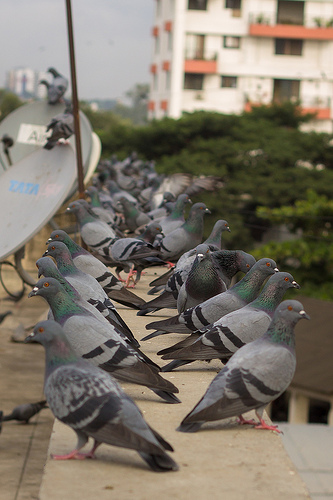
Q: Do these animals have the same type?
A: No, there are both pigeons and birds.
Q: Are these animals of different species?
A: Yes, they are pigeons and birds.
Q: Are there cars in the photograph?
A: No, there are no cars.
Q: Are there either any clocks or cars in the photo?
A: No, there are no cars or clocks.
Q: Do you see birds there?
A: Yes, there is a bird.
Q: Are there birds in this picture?
A: Yes, there is a bird.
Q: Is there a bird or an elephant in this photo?
A: Yes, there is a bird.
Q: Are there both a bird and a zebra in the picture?
A: No, there is a bird but no zebras.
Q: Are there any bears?
A: No, there are no bears.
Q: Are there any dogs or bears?
A: No, there are no bears or dogs.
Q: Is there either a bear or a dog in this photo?
A: No, there are no bears or dogs.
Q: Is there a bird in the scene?
A: Yes, there is a bird.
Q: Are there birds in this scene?
A: Yes, there is a bird.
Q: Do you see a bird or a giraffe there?
A: Yes, there is a bird.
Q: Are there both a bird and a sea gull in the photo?
A: No, there is a bird but no seagulls.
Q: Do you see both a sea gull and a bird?
A: No, there is a bird but no seagulls.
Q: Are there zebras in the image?
A: No, there are no zebras.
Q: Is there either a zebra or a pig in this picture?
A: No, there are no zebras or pigs.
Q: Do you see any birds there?
A: Yes, there is a bird.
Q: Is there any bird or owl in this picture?
A: Yes, there is a bird.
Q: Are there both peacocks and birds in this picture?
A: No, there is a bird but no peacocks.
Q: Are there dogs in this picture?
A: No, there are no dogs.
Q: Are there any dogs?
A: No, there are no dogs.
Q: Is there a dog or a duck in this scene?
A: No, there are no dogs or ducks.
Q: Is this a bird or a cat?
A: This is a bird.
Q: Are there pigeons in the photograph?
A: Yes, there is a pigeon.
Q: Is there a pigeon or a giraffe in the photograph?
A: Yes, there is a pigeon.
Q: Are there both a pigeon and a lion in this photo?
A: No, there is a pigeon but no lions.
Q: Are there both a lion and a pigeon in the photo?
A: No, there is a pigeon but no lions.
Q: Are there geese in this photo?
A: No, there are no geese.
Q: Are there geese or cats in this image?
A: No, there are no geese or cats.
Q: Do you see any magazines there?
A: No, there are no magazines.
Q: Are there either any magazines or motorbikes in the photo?
A: No, there are no magazines or motorbikes.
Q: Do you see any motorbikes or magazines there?
A: No, there are no magazines or motorbikes.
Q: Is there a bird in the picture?
A: Yes, there is a bird.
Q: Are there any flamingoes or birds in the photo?
A: Yes, there is a bird.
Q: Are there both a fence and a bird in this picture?
A: No, there is a bird but no fences.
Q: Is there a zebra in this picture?
A: No, there are no zebras.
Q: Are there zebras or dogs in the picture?
A: No, there are no zebras or dogs.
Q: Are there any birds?
A: Yes, there is a bird.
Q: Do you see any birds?
A: Yes, there is a bird.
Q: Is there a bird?
A: Yes, there is a bird.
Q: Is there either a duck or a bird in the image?
A: Yes, there is a bird.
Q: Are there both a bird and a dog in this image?
A: No, there is a bird but no dogs.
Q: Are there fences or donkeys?
A: No, there are no fences or donkeys.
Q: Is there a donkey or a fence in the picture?
A: No, there are no fences or donkeys.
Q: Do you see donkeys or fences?
A: No, there are no fences or donkeys.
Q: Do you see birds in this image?
A: Yes, there is a bird.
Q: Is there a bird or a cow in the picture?
A: Yes, there is a bird.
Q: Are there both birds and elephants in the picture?
A: No, there is a bird but no elephants.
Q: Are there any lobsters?
A: No, there are no lobsters.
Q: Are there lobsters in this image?
A: No, there are no lobsters.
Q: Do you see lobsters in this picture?
A: No, there are no lobsters.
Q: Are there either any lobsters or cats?
A: No, there are no lobsters or cats.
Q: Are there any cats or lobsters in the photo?
A: No, there are no lobsters or cats.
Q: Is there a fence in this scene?
A: No, there are no fences.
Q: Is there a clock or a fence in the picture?
A: No, there are no fences or clocks.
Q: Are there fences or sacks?
A: No, there are no fences or sacks.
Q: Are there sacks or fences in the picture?
A: No, there are no fences or sacks.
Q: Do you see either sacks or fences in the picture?
A: No, there are no fences or sacks.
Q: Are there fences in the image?
A: No, there are no fences.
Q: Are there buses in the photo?
A: No, there are no buses.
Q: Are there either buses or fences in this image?
A: No, there are no buses or fences.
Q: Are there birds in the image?
A: Yes, there is a bird.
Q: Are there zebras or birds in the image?
A: Yes, there is a bird.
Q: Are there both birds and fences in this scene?
A: No, there is a bird but no fences.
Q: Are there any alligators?
A: No, there are no alligators.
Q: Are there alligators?
A: No, there are no alligators.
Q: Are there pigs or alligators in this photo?
A: No, there are no alligators or pigs.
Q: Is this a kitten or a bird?
A: This is a bird.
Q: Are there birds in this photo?
A: Yes, there is a bird.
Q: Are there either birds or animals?
A: Yes, there is a bird.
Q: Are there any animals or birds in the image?
A: Yes, there is a bird.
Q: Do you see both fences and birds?
A: No, there is a bird but no fences.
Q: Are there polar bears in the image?
A: No, there are no polar bears.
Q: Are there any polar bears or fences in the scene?
A: No, there are no polar bears or fences.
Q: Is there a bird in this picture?
A: Yes, there is a bird.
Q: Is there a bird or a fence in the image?
A: Yes, there is a bird.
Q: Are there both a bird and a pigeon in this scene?
A: Yes, there are both a bird and a pigeon.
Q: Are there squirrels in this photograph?
A: No, there are no squirrels.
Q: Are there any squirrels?
A: No, there are no squirrels.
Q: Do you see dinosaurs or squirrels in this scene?
A: No, there are no squirrels or dinosaurs.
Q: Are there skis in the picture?
A: No, there are no skis.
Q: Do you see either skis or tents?
A: No, there are no skis or tents.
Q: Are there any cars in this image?
A: No, there are no cars.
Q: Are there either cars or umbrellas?
A: No, there are no cars or umbrellas.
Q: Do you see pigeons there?
A: Yes, there is a pigeon.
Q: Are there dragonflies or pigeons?
A: Yes, there is a pigeon.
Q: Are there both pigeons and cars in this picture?
A: No, there is a pigeon but no cars.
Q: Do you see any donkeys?
A: No, there are no donkeys.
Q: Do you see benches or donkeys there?
A: No, there are no donkeys or benches.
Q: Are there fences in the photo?
A: No, there are no fences.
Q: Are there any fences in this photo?
A: No, there are no fences.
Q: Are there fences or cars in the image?
A: No, there are no fences or cars.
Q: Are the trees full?
A: Yes, the trees are full.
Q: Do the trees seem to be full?
A: Yes, the trees are full.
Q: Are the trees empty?
A: No, the trees are full.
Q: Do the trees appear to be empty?
A: No, the trees are full.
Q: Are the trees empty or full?
A: The trees are full.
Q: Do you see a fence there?
A: No, there are no fences.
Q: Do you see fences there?
A: No, there are no fences.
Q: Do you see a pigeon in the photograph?
A: Yes, there is a pigeon.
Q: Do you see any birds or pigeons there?
A: Yes, there is a pigeon.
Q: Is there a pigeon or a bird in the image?
A: Yes, there is a pigeon.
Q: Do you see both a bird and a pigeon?
A: Yes, there are both a pigeon and a bird.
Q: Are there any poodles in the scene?
A: No, there are no poodles.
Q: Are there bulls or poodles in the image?
A: No, there are no poodles or bulls.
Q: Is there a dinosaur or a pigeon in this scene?
A: Yes, there is a pigeon.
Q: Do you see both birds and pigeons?
A: Yes, there are both a pigeon and birds.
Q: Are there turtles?
A: No, there are no turtles.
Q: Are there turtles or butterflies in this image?
A: No, there are no turtles or butterflies.